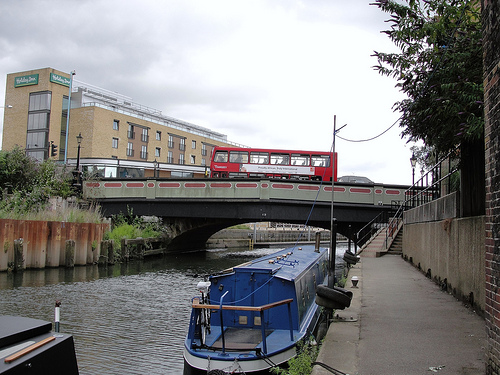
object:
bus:
[203, 144, 340, 188]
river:
[0, 240, 328, 373]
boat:
[182, 243, 335, 374]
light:
[321, 113, 351, 280]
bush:
[49, 161, 73, 191]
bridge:
[75, 168, 443, 223]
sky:
[0, 0, 442, 186]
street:
[304, 232, 497, 375]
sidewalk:
[310, 254, 492, 374]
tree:
[368, 1, 498, 176]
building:
[0, 67, 248, 178]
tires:
[312, 281, 356, 308]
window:
[269, 151, 291, 165]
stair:
[351, 196, 404, 257]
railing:
[346, 206, 382, 257]